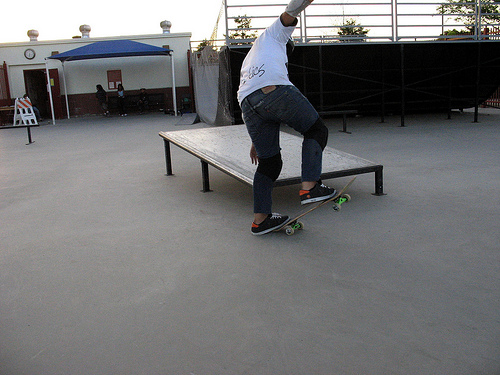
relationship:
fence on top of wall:
[223, 0, 499, 46] [224, 46, 497, 131]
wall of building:
[0, 32, 196, 99] [0, 19, 195, 121]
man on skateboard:
[233, 2, 345, 235] [253, 170, 356, 245]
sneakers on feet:
[253, 181, 341, 237] [245, 152, 335, 238]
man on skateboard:
[233, 2, 345, 235] [269, 174, 359, 236]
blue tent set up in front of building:
[53, 37, 175, 127] [0, 19, 195, 121]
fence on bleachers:
[223, 0, 499, 46] [190, 0, 483, 123]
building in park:
[0, 19, 195, 127] [0, 0, 499, 375]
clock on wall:
[22, 47, 37, 62] [0, 32, 196, 122]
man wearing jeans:
[233, 2, 345, 235] [216, 90, 401, 220]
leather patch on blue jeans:
[256, 83, 280, 97] [236, 83, 327, 212]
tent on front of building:
[49, 23, 158, 98] [4, 19, 348, 131]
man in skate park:
[233, 2, 345, 235] [0, 43, 500, 366]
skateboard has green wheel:
[270, 176, 357, 240] [334, 201, 341, 212]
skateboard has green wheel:
[270, 176, 357, 240] [346, 195, 351, 204]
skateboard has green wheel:
[270, 176, 357, 240] [285, 229, 292, 234]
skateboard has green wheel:
[270, 176, 357, 240] [295, 220, 304, 231]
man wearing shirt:
[233, 2, 345, 235] [236, 15, 298, 103]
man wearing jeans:
[233, 2, 345, 235] [240, 85, 327, 213]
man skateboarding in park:
[233, 2, 345, 235] [9, 20, 498, 370]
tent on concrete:
[49, 23, 158, 98] [1, 46, 194, 124]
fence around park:
[176, 1, 456, 106] [9, 20, 498, 370]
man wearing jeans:
[233, 2, 345, 235] [246, 87, 334, 205]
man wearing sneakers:
[233, 2, 345, 235] [253, 208, 290, 237]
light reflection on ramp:
[157, 126, 222, 158] [157, 116, 385, 206]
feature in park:
[149, 125, 386, 198] [0, 0, 499, 375]